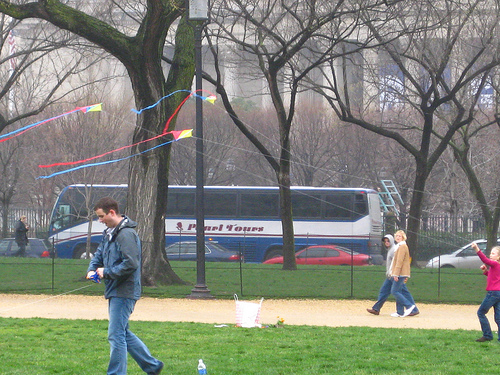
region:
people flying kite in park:
[8, 0, 494, 374]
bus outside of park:
[28, 136, 405, 296]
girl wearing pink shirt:
[456, 228, 498, 288]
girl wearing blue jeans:
[471, 289, 498, 330]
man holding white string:
[0, 253, 119, 324]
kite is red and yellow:
[95, 105, 205, 167]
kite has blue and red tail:
[36, 112, 205, 194]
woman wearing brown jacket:
[394, 234, 414, 281]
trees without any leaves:
[5, 3, 494, 283]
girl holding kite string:
[8, 35, 498, 311]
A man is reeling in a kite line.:
[0, 196, 163, 373]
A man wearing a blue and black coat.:
[85, 197, 163, 374]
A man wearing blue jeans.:
[84, 195, 164, 373]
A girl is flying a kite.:
[0, 101, 499, 341]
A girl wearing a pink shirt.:
[471, 240, 498, 341]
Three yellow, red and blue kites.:
[0, 88, 217, 181]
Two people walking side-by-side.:
[364, 229, 421, 319]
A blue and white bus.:
[44, 183, 384, 265]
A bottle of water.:
[195, 358, 206, 373]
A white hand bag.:
[232, 292, 264, 328]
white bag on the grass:
[233, 293, 265, 325]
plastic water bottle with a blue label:
[197, 359, 206, 373]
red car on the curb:
[262, 245, 375, 264]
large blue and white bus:
[49, 183, 384, 260]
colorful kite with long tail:
[37, 128, 193, 180]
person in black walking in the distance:
[13, 214, 28, 254]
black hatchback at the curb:
[1, 235, 50, 255]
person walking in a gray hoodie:
[367, 233, 419, 315]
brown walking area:
[2, 292, 496, 329]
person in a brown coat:
[393, 229, 417, 316]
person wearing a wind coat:
[68, 195, 170, 374]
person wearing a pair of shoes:
[389, 228, 418, 320]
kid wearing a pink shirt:
[461, 236, 498, 340]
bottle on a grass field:
[193, 353, 210, 373]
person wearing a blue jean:
[82, 196, 161, 373]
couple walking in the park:
[357, 225, 424, 323]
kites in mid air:
[17, 88, 239, 179]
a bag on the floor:
[227, 290, 271, 328]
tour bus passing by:
[35, 170, 395, 278]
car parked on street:
[259, 232, 374, 272]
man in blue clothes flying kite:
[74, 193, 176, 371]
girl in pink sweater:
[466, 236, 498, 350]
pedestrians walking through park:
[367, 225, 425, 320]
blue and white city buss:
[43, 174, 391, 270]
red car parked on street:
[260, 241, 372, 276]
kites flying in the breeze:
[5, 78, 247, 180]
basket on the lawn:
[204, 288, 295, 343]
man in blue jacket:
[76, 195, 172, 373]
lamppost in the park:
[166, 0, 240, 305]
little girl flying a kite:
[158, 119, 498, 345]